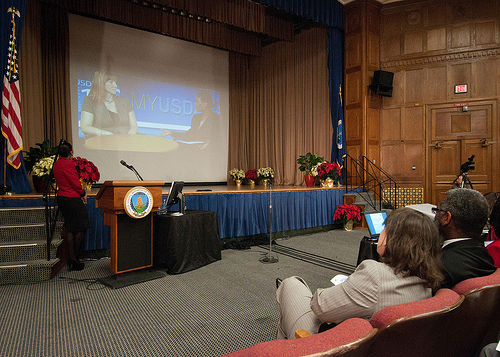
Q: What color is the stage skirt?
A: It is blue.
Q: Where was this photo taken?
A: In a room in a building.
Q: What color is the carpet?
A: Grey.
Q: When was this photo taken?
A: During a presentation.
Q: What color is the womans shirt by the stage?
A: Red.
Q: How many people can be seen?
A: 6.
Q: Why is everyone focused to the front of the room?
A: They are watching the screen.